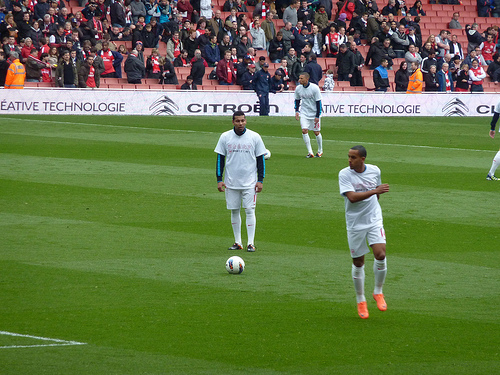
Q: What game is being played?
A: Baseball.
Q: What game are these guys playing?
A: Soccer.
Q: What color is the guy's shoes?
A: Orange.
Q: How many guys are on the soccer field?
A: 3.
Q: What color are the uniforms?
A: White.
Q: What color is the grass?
A: Green.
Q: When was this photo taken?
A: Day in the morning.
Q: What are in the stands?
A: Soccer fans.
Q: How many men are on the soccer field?
A: Three.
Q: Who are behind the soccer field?
A: A crowd of people.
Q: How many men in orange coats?
A: Two.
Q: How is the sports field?
A: It has green grass.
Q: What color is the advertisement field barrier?
A: White.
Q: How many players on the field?
A: 4.